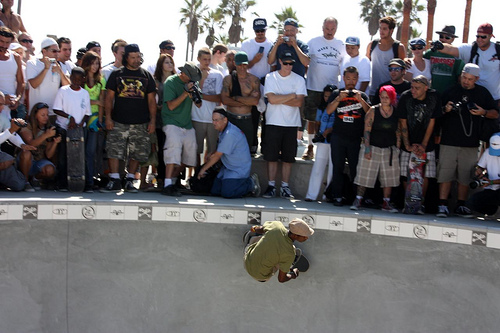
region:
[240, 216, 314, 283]
skater in green shirt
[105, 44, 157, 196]
person watching the skater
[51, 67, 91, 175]
person watching the skater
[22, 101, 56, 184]
person watching the skater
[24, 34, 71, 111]
person watching the skater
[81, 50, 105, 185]
person watching the skater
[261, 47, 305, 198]
person watching the skater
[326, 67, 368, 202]
person watching the skater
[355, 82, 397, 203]
person watching the skater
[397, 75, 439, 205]
person watching the skater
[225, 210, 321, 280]
a person on a skateboard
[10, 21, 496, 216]
people watching the man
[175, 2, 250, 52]
trees behind the people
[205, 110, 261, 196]
a man kneeling down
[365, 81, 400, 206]
a girl with pink hair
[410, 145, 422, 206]
a skateboard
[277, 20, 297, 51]
a man taking a picture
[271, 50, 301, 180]
a man with sunglasses on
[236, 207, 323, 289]
A skateboarder in a skate bowl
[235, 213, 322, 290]
A skateboarder in a skate bowl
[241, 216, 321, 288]
A skateboarder in a skate bowl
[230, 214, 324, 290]
A skateboarder in a skate bowl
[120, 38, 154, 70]
head of a person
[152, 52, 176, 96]
head of a person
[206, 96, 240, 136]
head of a person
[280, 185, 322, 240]
head of a person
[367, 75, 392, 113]
head of a person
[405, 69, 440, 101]
head of a person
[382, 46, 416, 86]
head of a person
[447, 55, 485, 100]
head of a person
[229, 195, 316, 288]
This person is skateboarding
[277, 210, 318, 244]
The person is wearing a hat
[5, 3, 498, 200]
Audience watching the skateboarder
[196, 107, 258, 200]
This person is on his knees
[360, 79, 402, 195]
She has pink hair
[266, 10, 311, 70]
He is taking a picture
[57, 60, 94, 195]
He is holding a skateboard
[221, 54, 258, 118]
He is not wearing a shirt